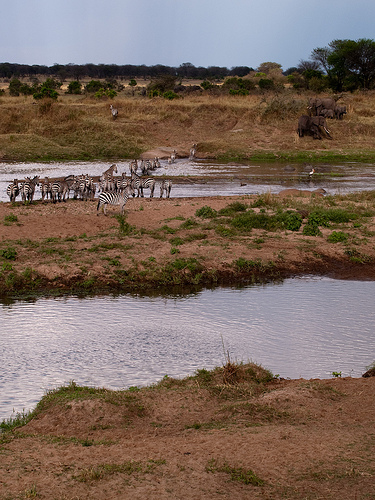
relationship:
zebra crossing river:
[7, 104, 198, 215] [0, 156, 375, 206]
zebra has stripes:
[7, 104, 198, 215] [97, 190, 117, 204]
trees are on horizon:
[1, 63, 255, 79] [1, 34, 374, 80]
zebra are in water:
[7, 104, 198, 215] [0, 156, 375, 206]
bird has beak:
[307, 167, 315, 175] [311, 168, 314, 173]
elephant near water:
[295, 113, 331, 138] [0, 156, 375, 206]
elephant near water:
[298, 98, 347, 140] [0, 156, 375, 206]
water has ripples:
[0, 265, 373, 429] [1, 295, 241, 424]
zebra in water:
[7, 104, 198, 215] [0, 156, 375, 206]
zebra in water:
[189, 146, 197, 160] [0, 156, 375, 206]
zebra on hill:
[7, 104, 198, 215] [0, 101, 371, 161]